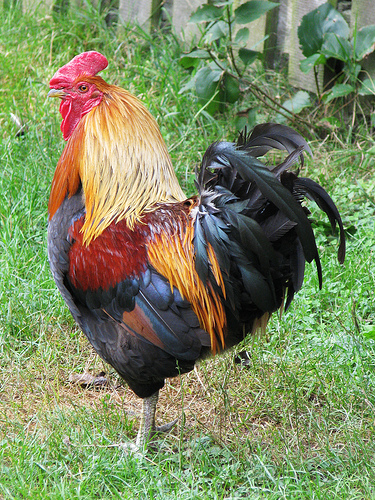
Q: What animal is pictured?
A: A bird.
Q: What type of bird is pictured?
A: A rooster.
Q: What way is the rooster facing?
A: Left.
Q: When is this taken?
A: Daytime.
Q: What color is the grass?
A: Green.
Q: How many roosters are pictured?
A: One.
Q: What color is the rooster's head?
A: Red.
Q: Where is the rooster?
A: In the yard.